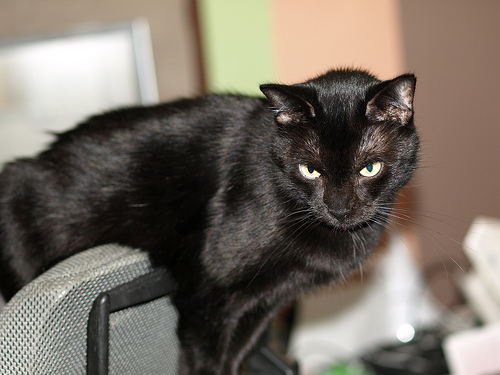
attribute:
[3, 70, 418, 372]
cat — sleepy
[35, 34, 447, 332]
cat — angry